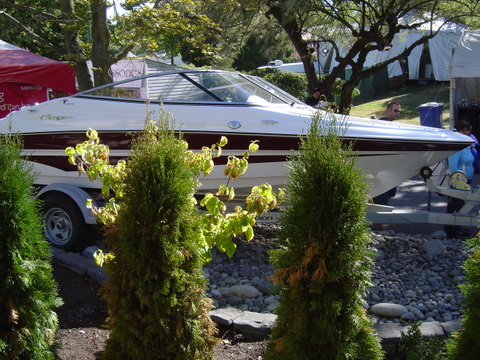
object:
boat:
[1, 69, 475, 250]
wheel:
[36, 192, 94, 252]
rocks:
[367, 300, 411, 318]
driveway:
[0, 198, 480, 357]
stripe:
[0, 131, 468, 150]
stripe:
[19, 152, 404, 174]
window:
[83, 71, 216, 103]